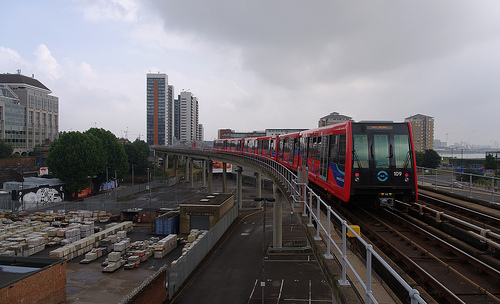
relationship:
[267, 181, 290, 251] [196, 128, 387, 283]
pillar hold bridge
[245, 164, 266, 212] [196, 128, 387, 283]
pillar hold bridge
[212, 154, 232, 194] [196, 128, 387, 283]
pillar hold bridge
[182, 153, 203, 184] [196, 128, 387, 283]
pillar hold bridge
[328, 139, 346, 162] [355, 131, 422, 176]
part of window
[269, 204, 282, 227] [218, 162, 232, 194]
part of pillar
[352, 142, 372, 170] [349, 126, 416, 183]
part of window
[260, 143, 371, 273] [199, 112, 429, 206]
railing next train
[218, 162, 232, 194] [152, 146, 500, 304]
pillar holding track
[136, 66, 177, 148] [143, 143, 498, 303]
building beyond tracks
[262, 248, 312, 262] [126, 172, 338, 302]
spaces on pavement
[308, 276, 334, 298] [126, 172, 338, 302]
spaces on pavement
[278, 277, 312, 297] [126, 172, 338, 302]
spaces on pavement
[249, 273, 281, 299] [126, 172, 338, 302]
spaces on pavement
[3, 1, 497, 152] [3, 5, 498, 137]
clouds in sky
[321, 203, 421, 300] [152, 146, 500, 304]
fence along track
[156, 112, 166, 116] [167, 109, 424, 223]
windows on train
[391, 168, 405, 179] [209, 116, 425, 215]
number on train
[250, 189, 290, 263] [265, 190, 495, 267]
light pole beneath tracks.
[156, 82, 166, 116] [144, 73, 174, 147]
windows on building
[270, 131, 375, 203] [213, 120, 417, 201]
red paint on train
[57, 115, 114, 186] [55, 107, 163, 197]
leaves on tree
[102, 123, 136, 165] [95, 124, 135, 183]
leaves on tree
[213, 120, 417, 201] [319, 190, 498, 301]
train on track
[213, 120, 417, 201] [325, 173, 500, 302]
train on track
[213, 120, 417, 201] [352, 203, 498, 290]
train on track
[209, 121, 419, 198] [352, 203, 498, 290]
red paint on track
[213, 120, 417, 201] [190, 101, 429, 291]
train on bridge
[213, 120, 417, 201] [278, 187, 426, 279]
train on bridge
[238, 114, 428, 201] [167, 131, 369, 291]
train moving on bridge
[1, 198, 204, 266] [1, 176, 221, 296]
cars on street